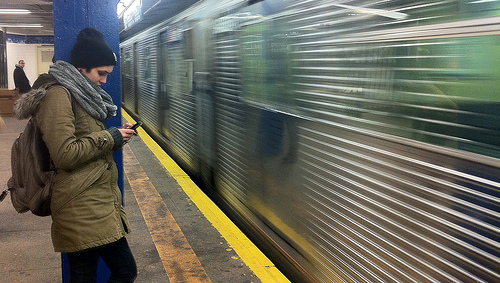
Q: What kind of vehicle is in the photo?
A: Train.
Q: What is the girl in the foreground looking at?
A: Cellular phone.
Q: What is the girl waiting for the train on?
A: Platform.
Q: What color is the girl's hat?
A: Black.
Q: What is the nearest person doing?
A: Looking at phone.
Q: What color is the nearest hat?
A: Black.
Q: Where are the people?
A: Train station.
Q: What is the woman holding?
A: Phone.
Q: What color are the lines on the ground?
A: Yellow.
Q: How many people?
A: Two.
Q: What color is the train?
A: Silver.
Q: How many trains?
A: One.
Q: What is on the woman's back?
A: Pack.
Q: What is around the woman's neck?
A: Scarf.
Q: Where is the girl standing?
A: Platform.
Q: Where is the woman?
A: At the tram station.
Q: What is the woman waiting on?
A: The tram.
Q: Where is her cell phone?
A: In her hand.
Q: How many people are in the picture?
A: Two.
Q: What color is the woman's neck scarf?
A: Gray.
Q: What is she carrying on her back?
A: A backpack.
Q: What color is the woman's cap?
A: Black.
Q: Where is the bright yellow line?
A: Alongside the tram tracks.